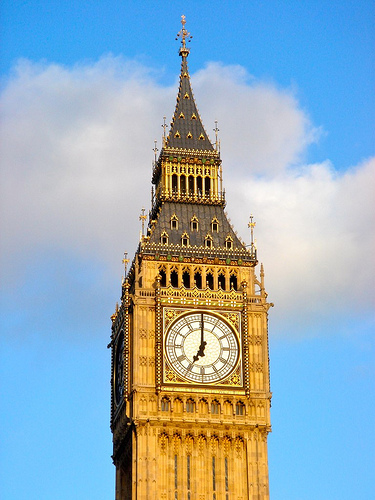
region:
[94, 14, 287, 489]
A gothic clock tower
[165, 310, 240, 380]
A clock with hands point to 7 o'clock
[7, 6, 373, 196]
Blue sky with white clouds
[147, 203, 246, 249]
A roof with 7 windows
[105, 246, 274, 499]
A yellow building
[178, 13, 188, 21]
Cross on the top of a building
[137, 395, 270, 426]
Gothic cornice design on a building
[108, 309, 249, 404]
Two clocks on the sides of a tower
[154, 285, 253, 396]
Elegant frame around a clock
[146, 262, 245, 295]
Seven open doorways in a building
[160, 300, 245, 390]
the face of the clock is white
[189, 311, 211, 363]
the hands of the are black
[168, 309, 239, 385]
the roman numerals are gold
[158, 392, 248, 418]
the clock's open arches have windows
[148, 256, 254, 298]
open arches are above the clock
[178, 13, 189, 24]
a cross on a ball is on the top of the tower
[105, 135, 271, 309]
parapets are everywhere on the tower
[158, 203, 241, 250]
windows are recessed into the roof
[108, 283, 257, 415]
two clocks are seen on the tower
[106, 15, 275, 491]
the clock tower is ornate in design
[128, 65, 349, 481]
a tall building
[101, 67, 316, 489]
a tall old building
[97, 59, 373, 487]
a tall building during the day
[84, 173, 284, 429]
a tall building with clock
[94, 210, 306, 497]
an old building with clock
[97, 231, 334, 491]
a building with large clock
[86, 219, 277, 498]
a building with large outside clock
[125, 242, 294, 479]
an old tall building with clock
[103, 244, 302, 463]
an old tall building with large clock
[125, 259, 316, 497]
an old tall building with outside clock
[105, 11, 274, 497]
a fancy gold colored clock tower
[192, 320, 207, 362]
black hands on a clock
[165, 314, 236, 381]
Roman numerals on a clock face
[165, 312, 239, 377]
a white clock face in a clock tower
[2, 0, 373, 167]
blue sky above the clouds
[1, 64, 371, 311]
puffy white clouds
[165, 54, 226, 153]
a dark gray pointed roof on the top of a clock tower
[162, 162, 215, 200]
arched openings under a pointed roof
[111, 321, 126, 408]
a partially visible clock on the side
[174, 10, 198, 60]
a spire on a clock tower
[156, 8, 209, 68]
A decoration is on the top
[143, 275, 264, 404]
The time is 7:00 clock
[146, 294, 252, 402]
The clock is white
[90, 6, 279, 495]
The clock is brown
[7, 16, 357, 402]
There is a cloud in the background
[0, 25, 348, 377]
The cloud is white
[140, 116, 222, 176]
Green and brown decorations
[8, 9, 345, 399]
It is sunny outside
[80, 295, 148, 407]
Another clock on the side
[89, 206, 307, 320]
This clock has a gate on it